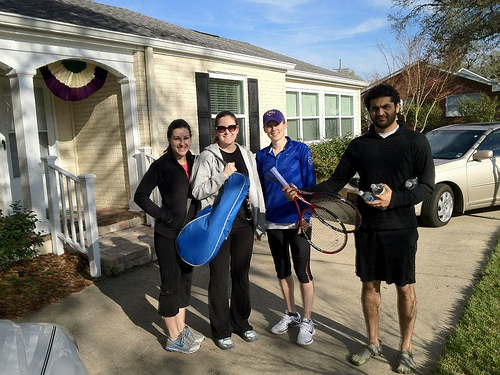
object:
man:
[281, 82, 437, 375]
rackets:
[267, 165, 348, 255]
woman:
[187, 109, 268, 351]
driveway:
[412, 208, 500, 375]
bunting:
[37, 59, 109, 102]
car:
[338, 121, 500, 228]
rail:
[38, 154, 102, 279]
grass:
[429, 225, 497, 375]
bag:
[173, 171, 251, 268]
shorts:
[353, 228, 421, 288]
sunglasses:
[214, 124, 237, 133]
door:
[0, 79, 64, 219]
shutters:
[207, 78, 244, 115]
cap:
[262, 109, 285, 128]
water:
[370, 183, 384, 200]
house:
[0, 0, 374, 289]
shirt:
[255, 135, 317, 223]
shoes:
[212, 336, 236, 350]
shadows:
[65, 236, 170, 353]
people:
[131, 117, 200, 355]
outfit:
[297, 120, 435, 231]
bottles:
[357, 190, 389, 211]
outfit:
[132, 143, 202, 240]